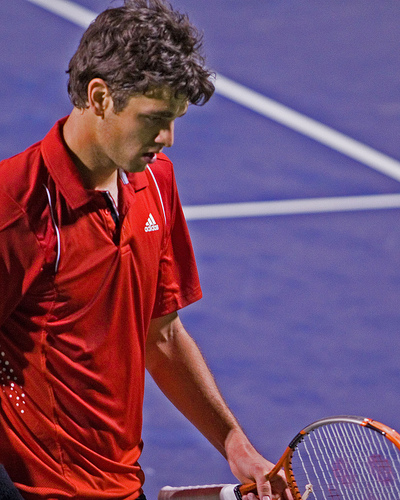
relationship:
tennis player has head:
[2, 4, 292, 499] [62, 14, 203, 174]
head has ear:
[62, 14, 203, 174] [89, 75, 110, 116]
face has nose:
[114, 95, 179, 169] [152, 125, 175, 146]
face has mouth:
[114, 95, 179, 169] [139, 147, 164, 163]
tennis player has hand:
[2, 4, 292, 499] [224, 436, 291, 499]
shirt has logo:
[0, 110, 203, 500] [146, 215, 160, 232]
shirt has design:
[0, 110, 203, 500] [0, 347, 34, 414]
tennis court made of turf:
[1, 2, 397, 499] [4, 2, 392, 498]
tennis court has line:
[1, 2, 397, 499] [37, 0, 399, 183]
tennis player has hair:
[2, 4, 292, 499] [67, 4, 211, 111]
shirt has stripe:
[0, 110, 203, 500] [36, 173, 70, 275]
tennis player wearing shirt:
[2, 4, 292, 499] [0, 110, 203, 500]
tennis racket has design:
[158, 409, 397, 500] [330, 448, 393, 489]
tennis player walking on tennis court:
[2, 4, 292, 499] [1, 2, 397, 499]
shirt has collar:
[0, 110, 203, 500] [39, 116, 153, 211]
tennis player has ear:
[2, 4, 292, 499] [89, 75, 110, 116]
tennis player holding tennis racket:
[2, 4, 292, 499] [158, 409, 397, 500]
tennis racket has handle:
[158, 409, 397, 500] [159, 475, 243, 500]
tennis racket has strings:
[158, 409, 397, 500] [295, 419, 394, 499]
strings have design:
[295, 419, 394, 499] [330, 448, 393, 489]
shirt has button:
[0, 110, 203, 500] [104, 202, 113, 215]